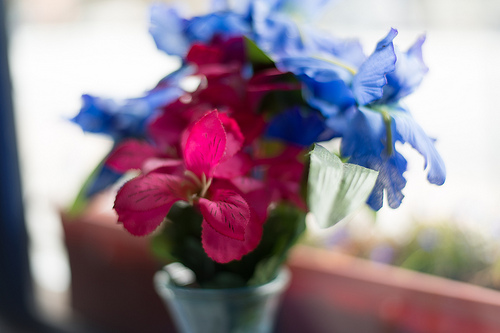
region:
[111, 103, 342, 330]
a beautiful rose flower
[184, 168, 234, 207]
a small white inside the flower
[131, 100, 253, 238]
a cute looking flower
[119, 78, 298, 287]
a rose flower in jug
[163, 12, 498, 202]
a blue colorful flowers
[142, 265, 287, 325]
a jug in the flowers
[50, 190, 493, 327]
a red basket in back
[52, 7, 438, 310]
a beautiful flower in jugs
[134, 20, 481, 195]
a combo of red and blue flowers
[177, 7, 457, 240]
blue flowers over red flowers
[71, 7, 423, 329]
small pot of flowers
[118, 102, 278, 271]
bright red flower with three petals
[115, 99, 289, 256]
dark pink flower with three petals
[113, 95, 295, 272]
bright pink flower with yellow center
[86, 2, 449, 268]
pink and blue flowers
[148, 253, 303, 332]
metal pot holding plant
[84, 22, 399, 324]
potted flowering plant on window sill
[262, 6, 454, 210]
drooping blue flowers with green center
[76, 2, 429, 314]
two types of flowers in one pot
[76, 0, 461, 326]
two types of flowers in same pot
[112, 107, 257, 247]
bright pink flower in a vase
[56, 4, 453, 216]
ruffly bright blue flowers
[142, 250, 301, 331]
round topped vase for flowers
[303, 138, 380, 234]
pointed green leaf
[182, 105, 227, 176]
single pink flower petal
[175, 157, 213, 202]
small white flower stamen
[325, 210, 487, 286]
blurry green lump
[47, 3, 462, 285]
bouquet of pink and blue flowers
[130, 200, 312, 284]
cur green flower stems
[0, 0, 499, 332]
bright white sun light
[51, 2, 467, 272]
blue and pink flowers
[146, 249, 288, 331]
glass vase flowers are in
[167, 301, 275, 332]
neck of glass vase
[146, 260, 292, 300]
lip of glass vase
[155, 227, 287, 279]
green stems of the floers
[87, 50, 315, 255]
pink flowers in the foreground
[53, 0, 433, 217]
blue flowers in the background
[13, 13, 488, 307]
window behind vase of flowers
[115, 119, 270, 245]
pink petals of the flower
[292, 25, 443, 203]
blue petals of the flower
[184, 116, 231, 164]
pink pedal on flower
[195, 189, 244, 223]
pink pedal on flower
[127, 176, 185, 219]
pink pedal on flower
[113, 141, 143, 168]
pink pedal on flower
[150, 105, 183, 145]
pink pedal on flower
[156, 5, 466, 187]
blue flowers in pot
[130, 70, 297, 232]
pink flowers in pot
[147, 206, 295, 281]
green stems of flowers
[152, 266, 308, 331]
glass pot under flowers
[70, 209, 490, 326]
red flower box in background